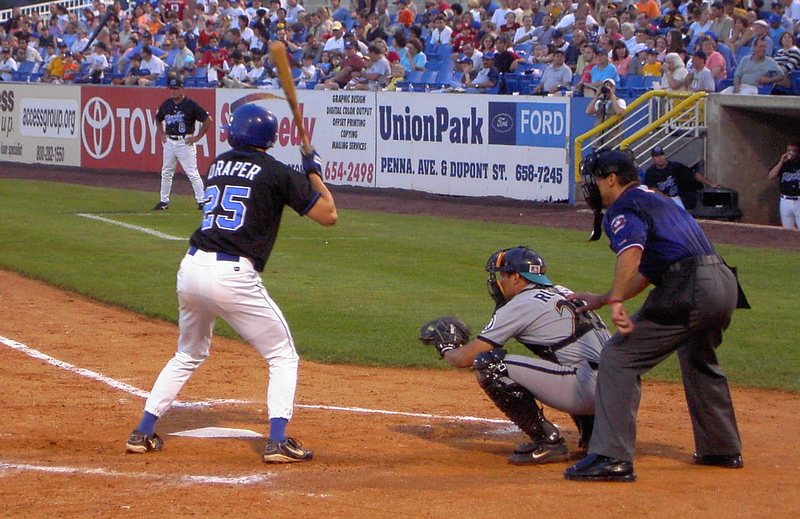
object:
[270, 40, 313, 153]
bat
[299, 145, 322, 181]
glove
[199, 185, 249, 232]
number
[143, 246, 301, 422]
pants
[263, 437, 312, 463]
shoe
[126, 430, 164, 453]
shoe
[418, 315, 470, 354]
mitt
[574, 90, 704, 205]
stairs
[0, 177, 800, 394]
grass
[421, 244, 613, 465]
catcher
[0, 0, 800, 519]
field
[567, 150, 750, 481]
umpire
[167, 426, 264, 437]
diamond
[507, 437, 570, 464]
cleat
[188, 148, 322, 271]
shirt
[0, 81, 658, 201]
wall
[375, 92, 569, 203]
bleacher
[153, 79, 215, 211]
body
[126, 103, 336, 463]
body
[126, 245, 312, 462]
human body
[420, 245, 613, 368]
human body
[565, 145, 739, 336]
human body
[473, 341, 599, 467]
human body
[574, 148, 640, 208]
human body